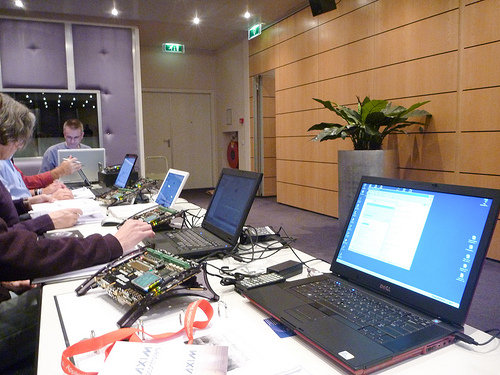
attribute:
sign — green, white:
[156, 38, 187, 58]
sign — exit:
[160, 40, 191, 55]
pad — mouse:
[285, 291, 336, 328]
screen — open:
[114, 157, 136, 187]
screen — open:
[156, 170, 186, 209]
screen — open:
[203, 174, 256, 236]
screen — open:
[335, 181, 493, 308]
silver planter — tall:
[336, 150, 399, 240]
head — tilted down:
[61, 120, 84, 149]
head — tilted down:
[1, 92, 36, 159]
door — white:
[147, 92, 225, 189]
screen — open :
[330, 180, 476, 311]